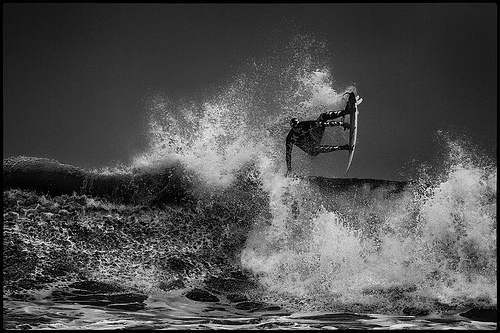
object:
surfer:
[285, 91, 352, 174]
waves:
[0, 154, 499, 312]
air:
[6, 5, 94, 55]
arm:
[285, 132, 296, 168]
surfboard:
[341, 91, 364, 174]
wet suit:
[285, 120, 325, 168]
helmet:
[289, 117, 300, 129]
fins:
[348, 91, 364, 110]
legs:
[316, 110, 346, 153]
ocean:
[0, 227, 499, 332]